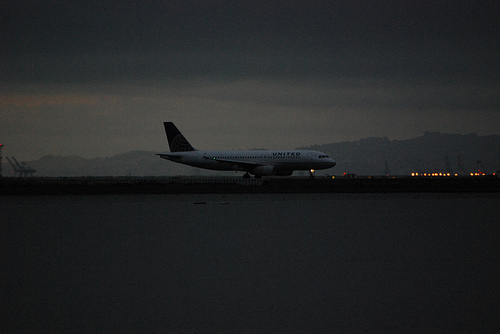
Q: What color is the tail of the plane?
A: Blue and grey.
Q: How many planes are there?
A: 1.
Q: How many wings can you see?
A: One.